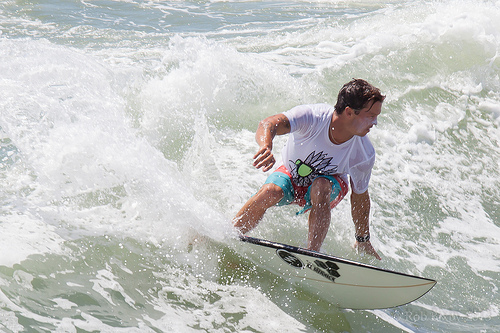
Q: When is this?
A: Daytime.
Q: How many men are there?
A: One.